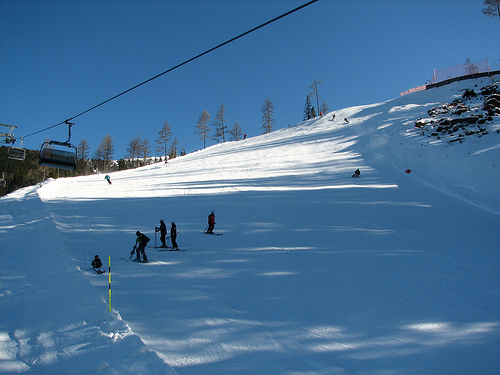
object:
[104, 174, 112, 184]
person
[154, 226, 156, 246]
pole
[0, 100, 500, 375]
slope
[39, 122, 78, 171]
chair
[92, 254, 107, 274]
person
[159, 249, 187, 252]
skis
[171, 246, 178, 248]
feet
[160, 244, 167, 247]
feet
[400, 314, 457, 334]
sunlight shining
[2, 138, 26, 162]
chair lift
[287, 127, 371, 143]
shadow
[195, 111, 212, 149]
pine tree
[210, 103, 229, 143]
pine tree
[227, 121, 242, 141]
pine tree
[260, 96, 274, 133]
pine tree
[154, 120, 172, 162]
pine tree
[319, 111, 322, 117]
person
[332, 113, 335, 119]
person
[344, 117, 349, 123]
person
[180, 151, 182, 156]
person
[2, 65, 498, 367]
mountain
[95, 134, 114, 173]
tree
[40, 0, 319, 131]
cable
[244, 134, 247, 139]
person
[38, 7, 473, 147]
sky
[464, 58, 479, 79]
trees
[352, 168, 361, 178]
person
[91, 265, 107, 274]
sled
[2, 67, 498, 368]
snow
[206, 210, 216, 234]
people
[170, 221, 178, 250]
people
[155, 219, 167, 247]
people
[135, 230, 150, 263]
people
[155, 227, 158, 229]
hand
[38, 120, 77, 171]
lift